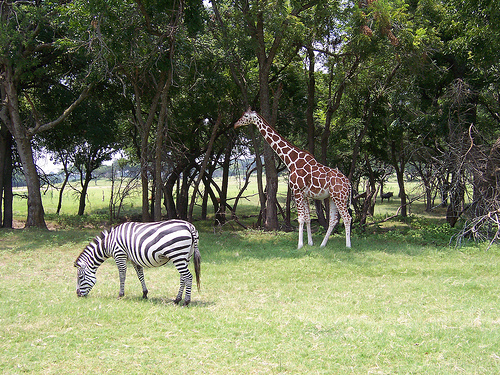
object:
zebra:
[72, 218, 204, 306]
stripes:
[118, 223, 137, 247]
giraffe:
[233, 104, 355, 248]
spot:
[288, 150, 299, 162]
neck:
[253, 114, 301, 172]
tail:
[184, 222, 202, 294]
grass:
[0, 229, 499, 374]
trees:
[0, 2, 109, 230]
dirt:
[12, 220, 25, 228]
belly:
[125, 235, 168, 268]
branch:
[27, 84, 91, 135]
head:
[233, 106, 259, 129]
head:
[73, 264, 98, 297]